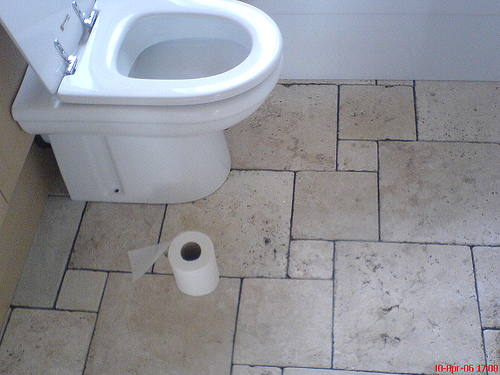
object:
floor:
[0, 80, 499, 374]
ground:
[278, 78, 498, 212]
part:
[336, 138, 378, 171]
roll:
[126, 230, 220, 297]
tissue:
[126, 231, 220, 297]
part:
[167, 230, 220, 297]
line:
[328, 238, 336, 368]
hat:
[127, 230, 222, 297]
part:
[126, 232, 166, 286]